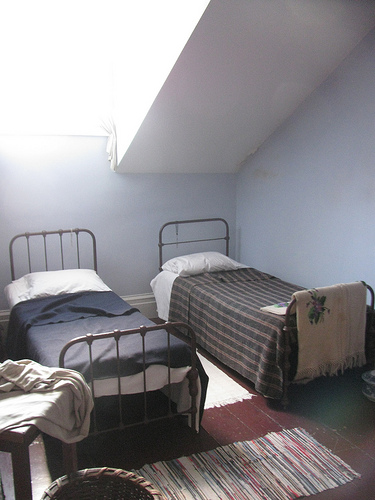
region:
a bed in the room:
[132, 196, 362, 381]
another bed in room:
[10, 221, 173, 399]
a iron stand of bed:
[78, 329, 179, 389]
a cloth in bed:
[27, 373, 122, 458]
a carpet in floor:
[227, 415, 321, 495]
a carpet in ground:
[217, 423, 325, 495]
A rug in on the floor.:
[127, 428, 330, 499]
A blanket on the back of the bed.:
[276, 290, 372, 365]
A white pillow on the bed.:
[173, 244, 250, 272]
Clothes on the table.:
[0, 354, 100, 435]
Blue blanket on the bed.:
[47, 287, 146, 353]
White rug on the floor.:
[185, 331, 243, 418]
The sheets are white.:
[150, 274, 182, 310]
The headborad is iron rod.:
[13, 218, 120, 281]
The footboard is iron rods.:
[63, 337, 226, 431]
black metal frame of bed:
[158, 219, 233, 259]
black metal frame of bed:
[10, 225, 100, 279]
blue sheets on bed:
[26, 280, 161, 379]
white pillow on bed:
[31, 263, 98, 297]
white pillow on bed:
[174, 249, 227, 279]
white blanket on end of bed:
[287, 282, 370, 378]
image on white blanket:
[305, 293, 326, 324]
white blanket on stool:
[0, 365, 90, 430]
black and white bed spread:
[193, 269, 274, 338]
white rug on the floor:
[204, 375, 250, 414]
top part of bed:
[9, 215, 93, 272]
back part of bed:
[69, 332, 207, 390]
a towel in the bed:
[286, 271, 372, 375]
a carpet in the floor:
[207, 429, 291, 491]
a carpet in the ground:
[216, 421, 369, 498]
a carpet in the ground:
[210, 411, 306, 482]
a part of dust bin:
[58, 450, 191, 499]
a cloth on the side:
[22, 343, 129, 493]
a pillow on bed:
[21, 258, 104, 320]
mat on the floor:
[147, 425, 359, 498]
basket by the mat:
[38, 465, 171, 498]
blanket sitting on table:
[0, 364, 100, 445]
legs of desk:
[0, 419, 73, 490]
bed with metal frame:
[0, 231, 202, 437]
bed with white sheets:
[6, 225, 208, 435]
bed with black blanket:
[9, 227, 202, 432]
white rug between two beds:
[170, 340, 248, 405]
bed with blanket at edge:
[151, 213, 373, 399]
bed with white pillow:
[145, 210, 369, 396]